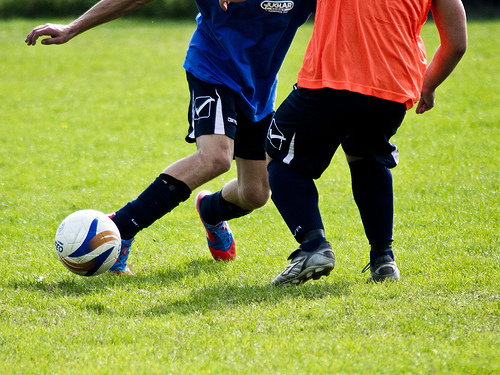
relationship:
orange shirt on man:
[297, 0, 426, 107] [258, 0, 471, 285]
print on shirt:
[188, 89, 220, 126] [183, 0, 317, 122]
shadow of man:
[0, 223, 499, 375] [258, 0, 471, 285]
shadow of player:
[0, 223, 499, 375] [123, 0, 286, 249]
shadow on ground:
[0, 223, 499, 375] [34, 296, 494, 368]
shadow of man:
[79, 280, 347, 325] [31, 0, 311, 275]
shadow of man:
[0, 223, 499, 375] [31, 0, 311, 275]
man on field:
[258, 1, 470, 294] [2, 15, 499, 374]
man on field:
[31, 0, 311, 275] [2, 15, 499, 374]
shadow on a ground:
[0, 223, 499, 375] [0, 16, 498, 373]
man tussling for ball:
[21, 0, 317, 275] [53, 207, 123, 277]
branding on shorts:
[190, 94, 217, 126] [185, 72, 274, 162]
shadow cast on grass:
[0, 223, 499, 375] [26, 318, 499, 369]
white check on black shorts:
[266, 124, 288, 146] [267, 83, 413, 175]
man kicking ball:
[21, 0, 317, 275] [55, 208, 125, 277]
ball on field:
[55, 208, 125, 277] [2, 15, 499, 374]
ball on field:
[42, 193, 137, 293] [140, 296, 442, 350]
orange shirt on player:
[297, 0, 426, 107] [61, 13, 286, 290]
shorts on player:
[189, 87, 276, 163] [25, 7, 310, 272]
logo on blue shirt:
[260, 0, 295, 17] [184, 2, 313, 120]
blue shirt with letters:
[184, 2, 313, 121] [261, 0, 290, 15]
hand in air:
[23, 19, 66, 48] [1, 2, 177, 83]